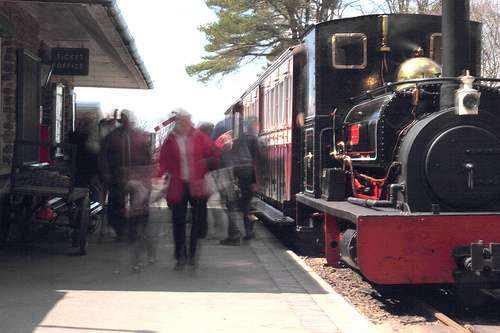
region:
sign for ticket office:
[21, 25, 117, 89]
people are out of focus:
[71, 84, 301, 290]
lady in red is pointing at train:
[115, 107, 260, 295]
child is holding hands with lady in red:
[113, 160, 187, 282]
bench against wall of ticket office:
[36, 184, 108, 256]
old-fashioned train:
[210, 80, 492, 314]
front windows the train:
[301, 11, 497, 91]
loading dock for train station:
[98, 78, 350, 316]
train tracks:
[324, 263, 498, 331]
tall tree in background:
[185, 4, 372, 97]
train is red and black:
[225, 0, 498, 317]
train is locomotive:
[316, 14, 499, 286]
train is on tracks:
[373, 284, 495, 328]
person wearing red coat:
[151, 127, 226, 204]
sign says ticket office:
[51, 48, 91, 75]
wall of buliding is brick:
[1, 16, 76, 211]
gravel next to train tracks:
[304, 254, 464, 330]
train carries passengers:
[222, 52, 300, 234]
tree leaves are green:
[183, 18, 317, 73]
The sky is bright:
[2, 0, 499, 132]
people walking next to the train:
[91, 84, 274, 281]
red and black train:
[208, 3, 482, 296]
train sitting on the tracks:
[216, 11, 499, 314]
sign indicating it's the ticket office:
[47, 37, 96, 78]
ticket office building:
[2, 0, 149, 283]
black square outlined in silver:
[329, 26, 374, 73]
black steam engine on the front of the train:
[306, 0, 498, 215]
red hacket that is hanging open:
[147, 128, 222, 204]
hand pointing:
[201, 113, 241, 164]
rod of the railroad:
[412, 293, 470, 328]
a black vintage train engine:
[299, 8, 496, 294]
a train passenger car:
[256, 44, 295, 222]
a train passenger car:
[230, 78, 261, 209]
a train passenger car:
[220, 95, 242, 207]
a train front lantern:
[451, 67, 479, 118]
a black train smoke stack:
[432, 0, 470, 83]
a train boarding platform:
[1, 127, 341, 327]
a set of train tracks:
[412, 273, 497, 330]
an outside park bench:
[28, 161, 105, 244]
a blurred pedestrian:
[152, 108, 232, 273]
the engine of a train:
[303, 14, 498, 285]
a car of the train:
[263, 40, 296, 244]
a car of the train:
[241, 84, 260, 150]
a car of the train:
[219, 104, 240, 139]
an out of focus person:
[159, 100, 231, 272]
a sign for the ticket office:
[45, 45, 92, 74]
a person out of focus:
[221, 116, 282, 244]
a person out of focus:
[102, 107, 155, 260]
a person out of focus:
[70, 109, 103, 232]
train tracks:
[428, 286, 498, 330]